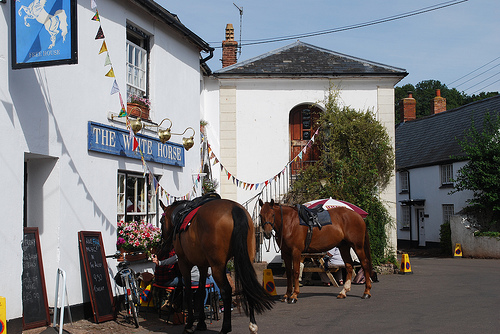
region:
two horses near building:
[133, 178, 385, 332]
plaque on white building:
[82, 119, 184, 170]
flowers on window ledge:
[108, 221, 164, 253]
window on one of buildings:
[433, 163, 458, 188]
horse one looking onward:
[257, 188, 384, 305]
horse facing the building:
[145, 181, 273, 328]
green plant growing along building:
[295, 85, 397, 271]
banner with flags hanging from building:
[203, 125, 330, 195]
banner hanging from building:
[2, 0, 83, 75]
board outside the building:
[76, 231, 114, 321]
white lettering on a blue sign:
[92, 128, 185, 165]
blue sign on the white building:
[78, 123, 194, 176]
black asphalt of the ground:
[412, 283, 475, 328]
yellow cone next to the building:
[398, 252, 420, 273]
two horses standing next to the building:
[145, 180, 382, 331]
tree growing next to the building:
[286, 103, 397, 275]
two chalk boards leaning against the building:
[1, 225, 119, 323]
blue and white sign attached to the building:
[11, 0, 81, 73]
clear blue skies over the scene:
[391, 25, 458, 59]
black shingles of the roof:
[262, 45, 355, 75]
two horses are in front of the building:
[121, 177, 396, 332]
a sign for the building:
[81, 113, 202, 168]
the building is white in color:
[50, 44, 202, 208]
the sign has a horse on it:
[14, 5, 79, 69]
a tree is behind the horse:
[315, 88, 392, 283]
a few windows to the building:
[109, 13, 185, 250]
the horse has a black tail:
[233, 202, 271, 324]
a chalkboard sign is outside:
[72, 223, 117, 319]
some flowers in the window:
[128, 78, 153, 124]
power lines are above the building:
[247, 1, 462, 46]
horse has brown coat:
[132, 173, 299, 328]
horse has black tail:
[148, 185, 298, 327]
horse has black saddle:
[282, 183, 339, 258]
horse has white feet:
[325, 265, 376, 304]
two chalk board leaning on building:
[2, 213, 138, 331]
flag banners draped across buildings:
[72, 14, 341, 216]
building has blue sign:
[69, 75, 205, 194]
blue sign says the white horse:
[78, 102, 203, 184]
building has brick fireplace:
[207, 15, 265, 98]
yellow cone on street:
[385, 229, 427, 291]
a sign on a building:
[91, 122, 188, 167]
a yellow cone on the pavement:
[396, 251, 413, 276]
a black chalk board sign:
[78, 232, 118, 323]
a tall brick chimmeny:
[218, 23, 240, 68]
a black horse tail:
[231, 201, 273, 320]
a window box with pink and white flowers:
[120, 221, 157, 260]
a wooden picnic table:
[281, 245, 348, 293]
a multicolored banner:
[196, 129, 328, 188]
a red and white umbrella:
[304, 196, 366, 218]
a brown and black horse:
[155, 193, 266, 332]